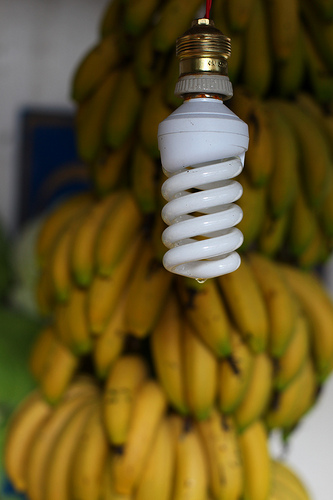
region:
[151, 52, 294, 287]
a hanging white light bulb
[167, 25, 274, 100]
the base of a light bulb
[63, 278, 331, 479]
a bundle of hanging bananas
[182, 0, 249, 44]
a red wire leading to a light bulb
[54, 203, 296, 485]
bananas hanging behind a light bulb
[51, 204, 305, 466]
lots of bananas that is in a bundle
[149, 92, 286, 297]
a twisted light bulb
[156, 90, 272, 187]
the white plastic on a light bulb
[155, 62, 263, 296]
a light bulb hanging in front of some bannanas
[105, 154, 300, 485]
a bunch of ripe bananas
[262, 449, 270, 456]
part of a banana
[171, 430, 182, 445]
edge of a banana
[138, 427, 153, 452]
part of a bunch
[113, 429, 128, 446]
a bunch of ripe bananas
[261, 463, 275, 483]
part of a wall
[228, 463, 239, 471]
edge of a banana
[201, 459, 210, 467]
side of a banana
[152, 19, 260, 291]
a white light bulb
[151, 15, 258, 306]
a coiled light bulb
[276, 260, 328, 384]
a single yellow banana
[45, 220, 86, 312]
a single yellow banana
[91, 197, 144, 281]
a single yellow banana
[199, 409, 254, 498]
a single yellow banana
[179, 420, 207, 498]
a single yellow banana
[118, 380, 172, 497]
a single yellow banana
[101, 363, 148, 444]
a single yellow banana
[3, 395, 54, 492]
a single yellow banana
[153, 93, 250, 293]
white CFL bulb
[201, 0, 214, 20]
red wire attached to the light socket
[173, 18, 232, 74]
gold colored metal light socket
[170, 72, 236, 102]
ceramic collar on the light socket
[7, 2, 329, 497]
lots of bananas hanging up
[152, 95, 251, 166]
base of the light bulb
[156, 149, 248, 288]
glass of the bulb shaped like cork screw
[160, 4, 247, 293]
light bulb hanging by the wire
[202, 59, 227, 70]
writing on the side of the socket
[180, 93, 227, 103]
some corrosion on the lightbulb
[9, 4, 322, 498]
a light in front handles of bananas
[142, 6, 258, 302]
a white light is hanging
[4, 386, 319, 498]
a handle of bananas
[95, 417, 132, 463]
tip of banana is black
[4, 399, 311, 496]
a handle of ripe bananas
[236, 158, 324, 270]
part of bananas color green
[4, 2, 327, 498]
handle of bananas on a stem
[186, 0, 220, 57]
a red wire above light socket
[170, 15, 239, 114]
a light socket color yellow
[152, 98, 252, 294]
a light shaped spiral